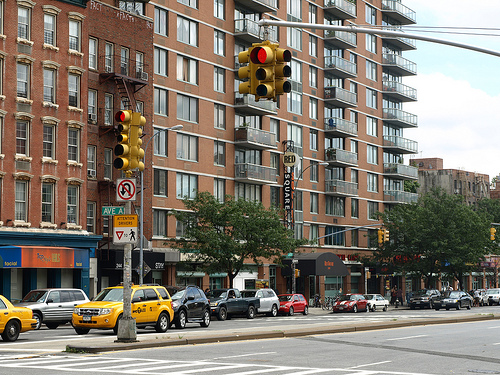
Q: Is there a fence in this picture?
A: No, there are no fences.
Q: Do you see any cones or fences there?
A: No, there are no fences or cones.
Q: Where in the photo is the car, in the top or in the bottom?
A: The car is in the bottom of the image.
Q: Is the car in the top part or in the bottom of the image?
A: The car is in the bottom of the image.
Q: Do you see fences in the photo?
A: No, there are no fences.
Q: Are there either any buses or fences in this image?
A: No, there are no fences or buses.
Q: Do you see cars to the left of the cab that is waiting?
A: No, the car is to the right of the cab.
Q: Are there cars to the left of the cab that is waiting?
A: No, the car is to the right of the cab.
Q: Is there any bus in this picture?
A: No, there are no buses.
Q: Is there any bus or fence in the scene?
A: No, there are no buses or fences.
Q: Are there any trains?
A: No, there are no trains.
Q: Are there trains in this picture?
A: No, there are no trains.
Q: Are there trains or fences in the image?
A: No, there are no trains or fences.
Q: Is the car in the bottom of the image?
A: Yes, the car is in the bottom of the image.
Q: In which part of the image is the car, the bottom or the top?
A: The car is in the bottom of the image.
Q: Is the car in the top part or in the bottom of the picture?
A: The car is in the bottom of the image.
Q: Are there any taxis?
A: Yes, there is a taxi.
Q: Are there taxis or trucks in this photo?
A: Yes, there is a taxi.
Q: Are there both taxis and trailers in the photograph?
A: No, there is a taxi but no trailers.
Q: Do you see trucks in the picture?
A: No, there are no trucks.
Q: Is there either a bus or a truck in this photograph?
A: No, there are no trucks or buses.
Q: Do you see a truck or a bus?
A: No, there are no trucks or buses.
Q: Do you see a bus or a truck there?
A: No, there are no trucks or buses.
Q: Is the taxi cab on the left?
A: Yes, the taxi cab is on the left of the image.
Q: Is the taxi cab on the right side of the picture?
A: No, the taxi cab is on the left of the image.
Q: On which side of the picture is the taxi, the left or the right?
A: The taxi is on the left of the image.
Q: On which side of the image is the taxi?
A: The taxi is on the left of the image.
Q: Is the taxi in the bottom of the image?
A: Yes, the taxi is in the bottom of the image.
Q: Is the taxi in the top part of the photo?
A: No, the taxi is in the bottom of the image.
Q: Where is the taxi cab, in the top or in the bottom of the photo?
A: The taxi cab is in the bottom of the image.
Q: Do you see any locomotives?
A: No, there are no locomotives.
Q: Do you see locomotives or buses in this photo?
A: No, there are no locomotives or buses.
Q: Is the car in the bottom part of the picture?
A: Yes, the car is in the bottom of the image.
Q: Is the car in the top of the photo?
A: No, the car is in the bottom of the image.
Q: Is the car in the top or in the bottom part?
A: The car is in the bottom of the image.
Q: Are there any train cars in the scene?
A: No, there are no train cars.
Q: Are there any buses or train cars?
A: No, there are no train cars or buses.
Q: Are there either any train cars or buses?
A: No, there are no train cars or buses.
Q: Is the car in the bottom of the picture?
A: Yes, the car is in the bottom of the image.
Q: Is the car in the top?
A: No, the car is in the bottom of the image.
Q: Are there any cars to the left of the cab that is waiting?
A: No, the car is to the right of the taxi.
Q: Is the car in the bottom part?
A: Yes, the car is in the bottom of the image.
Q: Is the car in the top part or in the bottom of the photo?
A: The car is in the bottom of the image.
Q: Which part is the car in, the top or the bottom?
A: The car is in the bottom of the image.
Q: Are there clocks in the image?
A: No, there are no clocks.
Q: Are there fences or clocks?
A: No, there are no clocks or fences.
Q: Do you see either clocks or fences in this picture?
A: No, there are no clocks or fences.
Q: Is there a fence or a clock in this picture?
A: No, there are no clocks or fences.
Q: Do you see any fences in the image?
A: No, there are no fences.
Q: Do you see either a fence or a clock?
A: No, there are no fences or clocks.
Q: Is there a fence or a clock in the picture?
A: No, there are no fences or clocks.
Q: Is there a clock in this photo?
A: No, there are no clocks.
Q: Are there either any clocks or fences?
A: No, there are no clocks or fences.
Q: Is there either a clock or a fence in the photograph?
A: No, there are no clocks or fences.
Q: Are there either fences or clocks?
A: No, there are no clocks or fences.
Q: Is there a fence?
A: No, there are no fences.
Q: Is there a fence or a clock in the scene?
A: No, there are no fences or clocks.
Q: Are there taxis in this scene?
A: Yes, there is a taxi.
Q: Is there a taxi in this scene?
A: Yes, there is a taxi.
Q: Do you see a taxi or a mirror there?
A: Yes, there is a taxi.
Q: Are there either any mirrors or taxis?
A: Yes, there is a taxi.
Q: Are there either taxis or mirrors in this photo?
A: Yes, there is a taxi.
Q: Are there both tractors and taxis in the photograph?
A: No, there is a taxi but no tractors.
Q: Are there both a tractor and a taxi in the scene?
A: No, there is a taxi but no tractors.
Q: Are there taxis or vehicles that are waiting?
A: Yes, the taxi is waiting.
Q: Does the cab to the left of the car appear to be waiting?
A: Yes, the taxi is waiting.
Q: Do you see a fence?
A: No, there are no fences.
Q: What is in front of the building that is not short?
A: The tree is in front of the building.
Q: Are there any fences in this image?
A: No, there are no fences.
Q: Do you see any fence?
A: No, there are no fences.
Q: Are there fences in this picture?
A: No, there are no fences.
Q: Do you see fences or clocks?
A: No, there are no fences or clocks.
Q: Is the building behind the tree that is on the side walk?
A: Yes, the building is behind the tree.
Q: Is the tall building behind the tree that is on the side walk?
A: Yes, the building is behind the tree.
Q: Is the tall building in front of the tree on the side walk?
A: No, the building is behind the tree.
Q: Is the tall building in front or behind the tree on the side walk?
A: The building is behind the tree.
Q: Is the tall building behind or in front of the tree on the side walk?
A: The building is behind the tree.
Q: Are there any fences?
A: No, there are no fences.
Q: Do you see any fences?
A: No, there are no fences.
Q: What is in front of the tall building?
A: The tree is in front of the building.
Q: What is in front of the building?
A: The tree is in front of the building.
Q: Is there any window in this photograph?
A: Yes, there is a window.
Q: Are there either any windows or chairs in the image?
A: Yes, there is a window.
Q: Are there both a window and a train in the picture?
A: No, there is a window but no trains.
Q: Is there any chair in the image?
A: No, there are no chairs.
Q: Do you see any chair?
A: No, there are no chairs.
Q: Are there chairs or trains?
A: No, there are no chairs or trains.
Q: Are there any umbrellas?
A: No, there are no umbrellas.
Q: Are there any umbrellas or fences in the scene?
A: No, there are no umbrellas or fences.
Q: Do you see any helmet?
A: No, there are no helmets.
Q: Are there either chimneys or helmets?
A: No, there are no helmets or chimneys.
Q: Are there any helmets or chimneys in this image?
A: No, there are no helmets or chimneys.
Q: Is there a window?
A: Yes, there is a window.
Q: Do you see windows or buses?
A: Yes, there is a window.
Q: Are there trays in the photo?
A: No, there are no trays.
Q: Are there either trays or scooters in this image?
A: No, there are no trays or scooters.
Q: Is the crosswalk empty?
A: Yes, the crosswalk is empty.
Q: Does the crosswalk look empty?
A: Yes, the crosswalk is empty.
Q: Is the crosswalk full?
A: No, the crosswalk is empty.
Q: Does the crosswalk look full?
A: No, the crosswalk is empty.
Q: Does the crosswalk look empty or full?
A: The crosswalk is empty.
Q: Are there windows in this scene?
A: Yes, there is a window.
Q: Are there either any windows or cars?
A: Yes, there is a window.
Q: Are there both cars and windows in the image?
A: Yes, there are both a window and a car.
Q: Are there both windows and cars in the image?
A: Yes, there are both a window and a car.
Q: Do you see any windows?
A: Yes, there is a window.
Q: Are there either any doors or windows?
A: Yes, there is a window.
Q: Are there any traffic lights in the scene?
A: Yes, there is a traffic light.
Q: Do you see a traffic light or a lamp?
A: Yes, there is a traffic light.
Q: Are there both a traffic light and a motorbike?
A: No, there is a traffic light but no motorcycles.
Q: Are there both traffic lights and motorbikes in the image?
A: No, there is a traffic light but no motorcycles.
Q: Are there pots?
A: No, there are no pots.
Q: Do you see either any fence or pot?
A: No, there are no pots or fences.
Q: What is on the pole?
A: The traffic light is on the pole.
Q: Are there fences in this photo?
A: No, there are no fences.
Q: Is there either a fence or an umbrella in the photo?
A: No, there are no fences or umbrellas.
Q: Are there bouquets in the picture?
A: No, there are no bouquets.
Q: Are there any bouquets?
A: No, there are no bouquets.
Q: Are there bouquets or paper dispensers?
A: No, there are no bouquets or paper dispensers.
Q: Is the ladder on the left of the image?
A: Yes, the ladder is on the left of the image.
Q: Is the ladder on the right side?
A: No, the ladder is on the left of the image.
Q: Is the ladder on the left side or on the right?
A: The ladder is on the left of the image.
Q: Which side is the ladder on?
A: The ladder is on the left of the image.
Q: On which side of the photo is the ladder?
A: The ladder is on the left of the image.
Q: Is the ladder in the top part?
A: Yes, the ladder is in the top of the image.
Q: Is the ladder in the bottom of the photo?
A: No, the ladder is in the top of the image.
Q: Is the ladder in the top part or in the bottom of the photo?
A: The ladder is in the top of the image.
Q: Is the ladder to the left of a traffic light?
A: Yes, the ladder is to the left of a traffic light.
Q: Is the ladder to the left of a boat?
A: No, the ladder is to the left of a traffic light.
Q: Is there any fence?
A: No, there are no fences.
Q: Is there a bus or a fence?
A: No, there are no fences or buses.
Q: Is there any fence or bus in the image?
A: No, there are no fences or buses.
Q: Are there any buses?
A: No, there are no buses.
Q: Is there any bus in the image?
A: No, there are no buses.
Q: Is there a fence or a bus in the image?
A: No, there are no buses or fences.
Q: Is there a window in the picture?
A: Yes, there is a window.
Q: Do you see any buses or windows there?
A: Yes, there is a window.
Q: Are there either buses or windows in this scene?
A: Yes, there is a window.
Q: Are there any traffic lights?
A: Yes, there is a traffic light.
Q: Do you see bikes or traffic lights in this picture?
A: Yes, there is a traffic light.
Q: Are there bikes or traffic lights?
A: Yes, there is a traffic light.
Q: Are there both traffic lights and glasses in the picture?
A: No, there is a traffic light but no glasses.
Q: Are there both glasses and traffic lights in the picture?
A: No, there is a traffic light but no glasses.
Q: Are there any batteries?
A: No, there are no batteries.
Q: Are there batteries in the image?
A: No, there are no batteries.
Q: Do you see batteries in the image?
A: No, there are no batteries.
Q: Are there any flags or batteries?
A: No, there are no batteries or flags.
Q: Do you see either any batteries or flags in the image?
A: No, there are no batteries or flags.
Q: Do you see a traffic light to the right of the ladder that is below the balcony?
A: Yes, there is a traffic light to the right of the ladder.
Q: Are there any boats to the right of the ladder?
A: No, there is a traffic light to the right of the ladder.